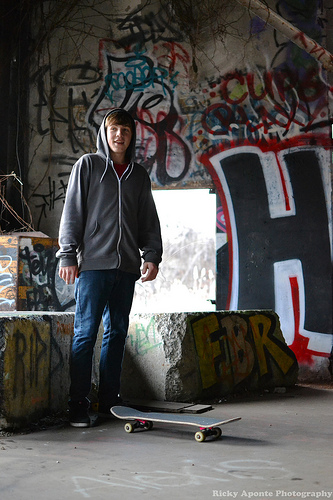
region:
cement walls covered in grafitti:
[0, 7, 332, 420]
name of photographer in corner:
[208, 485, 332, 499]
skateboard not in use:
[105, 389, 243, 446]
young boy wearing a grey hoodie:
[44, 112, 162, 269]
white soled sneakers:
[59, 394, 126, 430]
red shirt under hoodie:
[110, 155, 132, 183]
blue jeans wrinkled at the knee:
[55, 263, 143, 417]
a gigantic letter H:
[172, 134, 330, 391]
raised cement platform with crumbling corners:
[1, 298, 292, 405]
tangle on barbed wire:
[0, 152, 46, 234]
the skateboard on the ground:
[104, 397, 242, 444]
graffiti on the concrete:
[183, 307, 307, 387]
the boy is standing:
[58, 102, 149, 421]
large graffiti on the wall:
[193, 52, 330, 210]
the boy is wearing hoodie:
[52, 93, 160, 287]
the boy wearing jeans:
[62, 262, 123, 412]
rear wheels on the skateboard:
[123, 417, 149, 428]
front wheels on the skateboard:
[190, 426, 217, 436]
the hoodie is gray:
[61, 103, 155, 272]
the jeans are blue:
[78, 271, 130, 407]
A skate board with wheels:
[110, 406, 238, 442]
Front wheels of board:
[192, 423, 223, 441]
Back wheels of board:
[123, 418, 155, 431]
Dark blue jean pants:
[72, 265, 138, 428]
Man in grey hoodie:
[61, 110, 164, 281]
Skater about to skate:
[58, 110, 256, 458]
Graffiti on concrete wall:
[182, 309, 293, 388]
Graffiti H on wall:
[203, 134, 329, 348]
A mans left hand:
[136, 254, 158, 283]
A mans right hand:
[52, 251, 77, 283]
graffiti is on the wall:
[135, 26, 225, 94]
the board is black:
[110, 396, 239, 451]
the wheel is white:
[184, 430, 208, 445]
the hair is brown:
[110, 114, 129, 124]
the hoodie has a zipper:
[101, 171, 135, 275]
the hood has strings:
[96, 157, 151, 190]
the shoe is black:
[65, 408, 95, 432]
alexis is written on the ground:
[69, 458, 292, 492]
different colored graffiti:
[192, 315, 289, 385]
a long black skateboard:
[110, 400, 247, 443]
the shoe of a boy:
[66, 403, 91, 431]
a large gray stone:
[128, 309, 300, 399]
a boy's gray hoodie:
[55, 110, 162, 282]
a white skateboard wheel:
[193, 432, 203, 443]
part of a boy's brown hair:
[106, 107, 132, 128]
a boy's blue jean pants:
[69, 266, 135, 411]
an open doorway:
[132, 181, 215, 310]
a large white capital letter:
[218, 452, 289, 485]